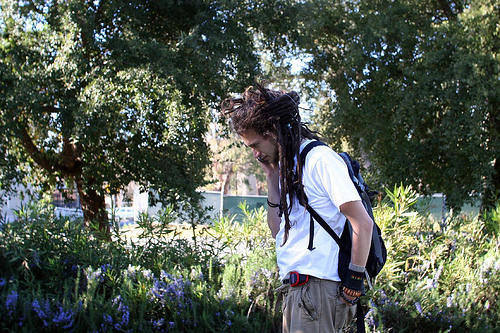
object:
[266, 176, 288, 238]
arm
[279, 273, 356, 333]
pants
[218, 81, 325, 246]
dreads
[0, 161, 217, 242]
hedge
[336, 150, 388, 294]
backpack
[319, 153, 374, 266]
arm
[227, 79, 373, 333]
man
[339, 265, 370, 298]
glove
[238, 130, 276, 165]
face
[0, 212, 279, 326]
plants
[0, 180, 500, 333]
flowers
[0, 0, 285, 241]
tree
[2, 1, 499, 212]
branches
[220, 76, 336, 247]
dreadlocks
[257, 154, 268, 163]
mobile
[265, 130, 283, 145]
ear